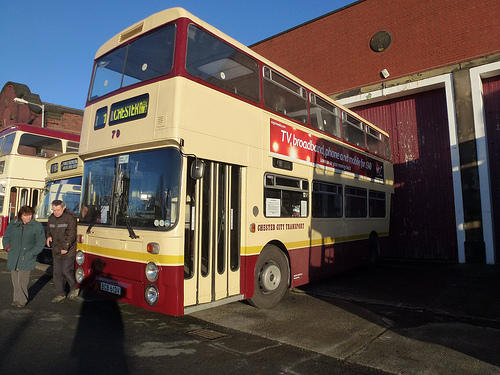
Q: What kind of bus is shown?
A: Double decker.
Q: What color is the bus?
A: Crimson and cream.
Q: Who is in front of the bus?
A: The man and the woman.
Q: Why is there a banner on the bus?
A: To advertise.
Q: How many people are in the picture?
A: Two.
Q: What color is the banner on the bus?
A: Red.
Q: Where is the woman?
A: By the man.